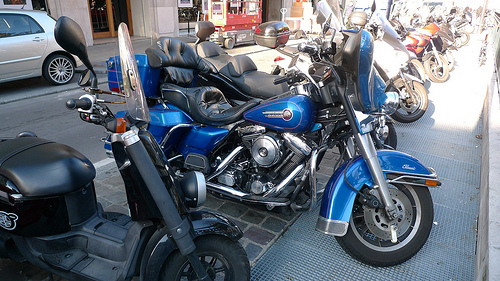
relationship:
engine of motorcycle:
[215, 118, 327, 213] [109, 28, 442, 269]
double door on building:
[87, 2, 141, 43] [7, 2, 282, 43]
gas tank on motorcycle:
[250, 93, 319, 135] [109, 28, 442, 269]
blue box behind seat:
[106, 50, 165, 93] [156, 34, 255, 128]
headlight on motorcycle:
[383, 88, 400, 119] [109, 28, 442, 269]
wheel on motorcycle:
[315, 152, 444, 264] [109, 28, 442, 269]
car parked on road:
[3, 8, 88, 88] [1, 67, 167, 164]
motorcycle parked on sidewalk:
[109, 28, 442, 269] [170, 16, 483, 255]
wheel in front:
[315, 152, 444, 264] [315, 18, 439, 263]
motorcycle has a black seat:
[109, 28, 442, 269] [156, 34, 255, 128]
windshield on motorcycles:
[119, 16, 150, 124] [1, 16, 248, 281]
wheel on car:
[47, 51, 80, 85] [3, 8, 88, 88]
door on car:
[2, 8, 44, 83] [3, 8, 88, 88]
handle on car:
[32, 31, 47, 48] [3, 8, 88, 88]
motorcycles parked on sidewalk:
[1, 1, 494, 280] [170, 16, 483, 255]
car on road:
[3, 8, 88, 88] [1, 67, 167, 164]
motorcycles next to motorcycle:
[1, 16, 248, 281] [109, 28, 442, 269]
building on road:
[7, 2, 282, 43] [1, 67, 167, 164]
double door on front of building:
[87, 2, 141, 43] [7, 2, 282, 43]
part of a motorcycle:
[249, 130, 285, 170] [109, 28, 442, 269]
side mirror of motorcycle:
[321, 13, 337, 45] [109, 28, 442, 269]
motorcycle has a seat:
[109, 28, 442, 269] [156, 34, 255, 128]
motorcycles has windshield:
[1, 16, 248, 281] [119, 16, 150, 124]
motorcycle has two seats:
[109, 28, 442, 269] [156, 34, 255, 128]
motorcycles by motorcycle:
[1, 16, 248, 281] [109, 28, 442, 269]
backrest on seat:
[155, 35, 202, 83] [156, 34, 255, 128]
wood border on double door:
[105, 1, 122, 41] [87, 2, 141, 43]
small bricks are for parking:
[95, 152, 295, 266] [1, 1, 494, 280]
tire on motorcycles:
[140, 215, 254, 280] [1, 16, 248, 281]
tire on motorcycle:
[315, 152, 444, 264] [109, 28, 442, 269]